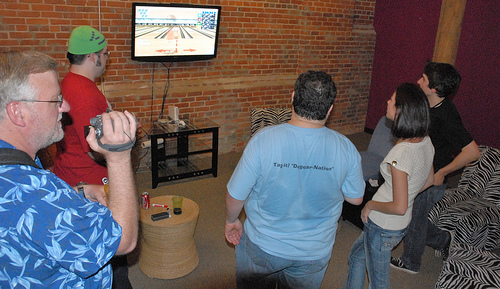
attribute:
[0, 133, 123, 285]
shirt — blue, Hawaiian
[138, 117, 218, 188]
tv stand — black 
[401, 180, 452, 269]
jeans — black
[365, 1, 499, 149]
wall — purple 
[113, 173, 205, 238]
can — red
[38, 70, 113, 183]
shirt — red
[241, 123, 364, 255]
shirt — blue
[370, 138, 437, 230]
blouse — white, knit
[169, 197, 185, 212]
glass — year, green, drinking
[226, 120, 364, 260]
t-shirt — light blue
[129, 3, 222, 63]
tv — wall-mounted